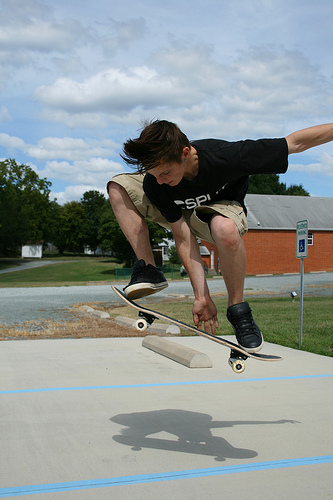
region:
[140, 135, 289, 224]
a black shirt on a boy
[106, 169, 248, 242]
tan shorts on a boy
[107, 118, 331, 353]
a boy jumping in the air on a skateboard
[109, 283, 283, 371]
a skateboard under a boy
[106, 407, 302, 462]
the shadow of a boy and skateboard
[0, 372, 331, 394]
a blue stripe painted on the concrete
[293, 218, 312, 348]
a parking sign next to a parking lot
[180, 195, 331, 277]
a red brick building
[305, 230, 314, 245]
a window in a building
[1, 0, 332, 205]
a bright blue cloud filled sky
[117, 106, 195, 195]
head of a person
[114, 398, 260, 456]
shadow of a person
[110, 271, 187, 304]
feet of a person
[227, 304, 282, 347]
feet of a person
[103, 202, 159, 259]
leg of a person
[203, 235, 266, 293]
leg of a person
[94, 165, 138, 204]
knee of a person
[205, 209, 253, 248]
knee of a person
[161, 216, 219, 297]
arm of a person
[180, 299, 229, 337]
hand of a person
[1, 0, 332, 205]
a blue and white cloudy sky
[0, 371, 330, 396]
a blue stripe painted on concrete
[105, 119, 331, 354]
a boy riding on a skateboard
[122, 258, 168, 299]
a black shoe on a boy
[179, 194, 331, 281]
a red brick building behind a boy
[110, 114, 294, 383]
person doing a trick in the air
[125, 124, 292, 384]
person doing a skateboard trick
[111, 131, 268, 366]
person performing a trick in mid air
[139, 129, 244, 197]
person wearing black shirt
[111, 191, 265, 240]
cargo shorts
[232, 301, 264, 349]
black shoe on left foot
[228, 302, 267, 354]
black shoe with white sole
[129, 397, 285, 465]
shadow of person doing a trick